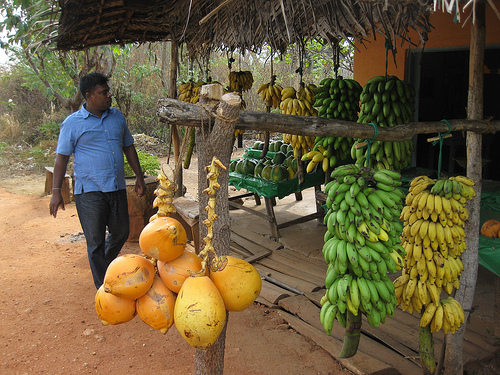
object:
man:
[48, 72, 148, 293]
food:
[384, 79, 396, 92]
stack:
[392, 175, 478, 336]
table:
[228, 169, 328, 238]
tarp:
[227, 170, 328, 201]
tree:
[0, 0, 165, 114]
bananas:
[410, 180, 435, 196]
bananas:
[417, 192, 430, 212]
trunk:
[156, 97, 500, 143]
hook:
[432, 119, 453, 181]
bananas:
[356, 275, 372, 304]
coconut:
[173, 269, 228, 351]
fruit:
[138, 216, 188, 264]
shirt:
[56, 102, 135, 196]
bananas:
[432, 179, 445, 194]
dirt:
[33, 290, 87, 358]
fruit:
[208, 255, 263, 313]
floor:
[227, 183, 500, 374]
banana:
[349, 183, 362, 199]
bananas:
[373, 171, 396, 185]